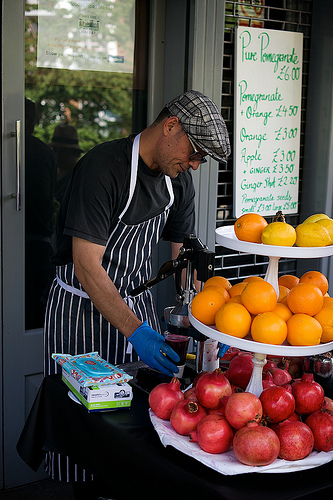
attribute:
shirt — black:
[55, 133, 196, 265]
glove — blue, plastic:
[129, 319, 180, 378]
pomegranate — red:
[225, 390, 263, 429]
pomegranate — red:
[260, 385, 298, 424]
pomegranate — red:
[233, 420, 279, 464]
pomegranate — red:
[149, 377, 183, 420]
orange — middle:
[191, 288, 229, 324]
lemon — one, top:
[260, 220, 296, 247]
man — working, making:
[45, 89, 229, 496]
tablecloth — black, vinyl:
[14, 369, 330, 493]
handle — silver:
[131, 248, 194, 331]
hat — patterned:
[166, 87, 231, 165]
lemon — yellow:
[294, 220, 331, 248]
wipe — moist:
[52, 351, 134, 386]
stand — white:
[151, 224, 329, 476]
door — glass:
[24, 2, 149, 329]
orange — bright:
[242, 279, 280, 317]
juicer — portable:
[130, 236, 217, 381]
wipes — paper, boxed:
[61, 364, 134, 413]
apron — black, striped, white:
[42, 132, 165, 375]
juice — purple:
[162, 330, 192, 381]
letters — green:
[237, 30, 300, 64]